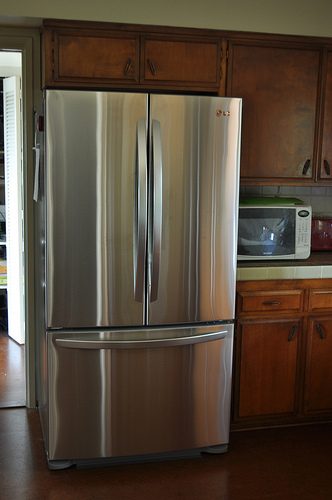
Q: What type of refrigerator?
A: A stainless steel 3 door refrigerator.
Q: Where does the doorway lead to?
A: The doorway leads to another room.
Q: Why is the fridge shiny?
A: It is a big silver fridge.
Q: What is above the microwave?
A: A wooden kitchen cabinet.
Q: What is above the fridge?
A: Two cabinets are above the fridge.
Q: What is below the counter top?
A: Two floor level cabinets.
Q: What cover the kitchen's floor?
A: Hardwood.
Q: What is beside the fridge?
A: A microwave.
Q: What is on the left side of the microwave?
A: A silver ridge.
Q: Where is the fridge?
A: In the kitchen.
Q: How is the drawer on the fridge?
A: Big.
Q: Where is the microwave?
A: On the counter.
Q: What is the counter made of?
A: Tile.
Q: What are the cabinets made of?
A: Wood.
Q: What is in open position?
A: The door.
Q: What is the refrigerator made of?
A: Stainless steel.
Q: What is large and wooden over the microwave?
A: A cabinet.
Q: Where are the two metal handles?
A: On the refrigerator.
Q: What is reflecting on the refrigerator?
A: Light.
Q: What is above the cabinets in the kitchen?
A: Section of a wall.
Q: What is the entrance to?
A: A kitchen.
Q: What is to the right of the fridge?
A: A microwave.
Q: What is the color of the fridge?
A: Silver.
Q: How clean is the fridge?
A: Very clean.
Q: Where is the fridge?
A: In the kitchen.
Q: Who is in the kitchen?
A: No one is in the kitchen.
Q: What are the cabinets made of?
A: They are made of wood.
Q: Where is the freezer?
A: It is at the bottom of the fridge.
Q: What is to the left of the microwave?
A: The refrigerator is to the left of the microwave.